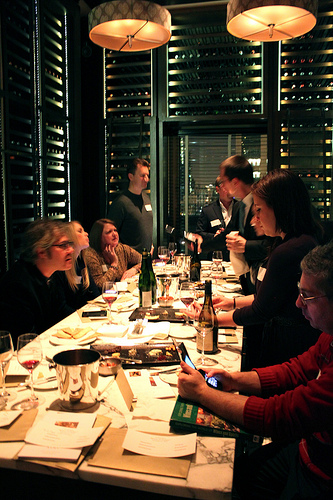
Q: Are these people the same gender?
A: No, they are both male and female.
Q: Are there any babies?
A: No, there are no babies.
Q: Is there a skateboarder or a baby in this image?
A: No, there are no babies or skateboarders.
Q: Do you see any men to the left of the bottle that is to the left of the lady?
A: Yes, there is a man to the left of the bottle.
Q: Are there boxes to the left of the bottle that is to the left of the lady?
A: No, there is a man to the left of the bottle.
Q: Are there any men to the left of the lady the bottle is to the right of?
A: Yes, there is a man to the left of the lady.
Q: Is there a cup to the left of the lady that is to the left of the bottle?
A: No, there is a man to the left of the lady.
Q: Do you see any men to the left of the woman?
A: Yes, there is a man to the left of the woman.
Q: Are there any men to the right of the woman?
A: No, the man is to the left of the woman.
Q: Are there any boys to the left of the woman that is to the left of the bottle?
A: No, there is a man to the left of the woman.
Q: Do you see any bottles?
A: Yes, there is a bottle.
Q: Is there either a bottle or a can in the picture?
A: Yes, there is a bottle.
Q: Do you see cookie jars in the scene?
A: No, there are no cookie jars.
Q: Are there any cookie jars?
A: No, there are no cookie jars.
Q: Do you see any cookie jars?
A: No, there are no cookie jars.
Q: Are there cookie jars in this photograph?
A: No, there are no cookie jars.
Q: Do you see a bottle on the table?
A: Yes, there is a bottle on the table.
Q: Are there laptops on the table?
A: No, there is a bottle on the table.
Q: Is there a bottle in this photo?
A: Yes, there is a bottle.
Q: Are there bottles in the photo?
A: Yes, there is a bottle.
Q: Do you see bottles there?
A: Yes, there is a bottle.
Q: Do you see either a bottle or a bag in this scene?
A: Yes, there is a bottle.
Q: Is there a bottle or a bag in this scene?
A: Yes, there is a bottle.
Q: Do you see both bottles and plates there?
A: Yes, there are both a bottle and a plate.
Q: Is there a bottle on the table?
A: Yes, there is a bottle on the table.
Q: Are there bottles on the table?
A: Yes, there is a bottle on the table.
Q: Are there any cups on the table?
A: No, there is a bottle on the table.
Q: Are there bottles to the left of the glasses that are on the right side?
A: Yes, there is a bottle to the left of the glasses.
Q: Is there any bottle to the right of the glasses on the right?
A: No, the bottle is to the left of the glasses.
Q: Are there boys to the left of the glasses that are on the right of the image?
A: No, there is a bottle to the left of the glasses.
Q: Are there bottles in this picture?
A: Yes, there is a bottle.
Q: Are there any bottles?
A: Yes, there is a bottle.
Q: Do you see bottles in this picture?
A: Yes, there is a bottle.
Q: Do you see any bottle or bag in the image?
A: Yes, there is a bottle.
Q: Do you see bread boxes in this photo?
A: No, there are no bread boxes.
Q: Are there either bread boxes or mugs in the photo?
A: No, there are no bread boxes or mugs.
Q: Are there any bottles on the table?
A: Yes, there is a bottle on the table.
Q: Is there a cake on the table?
A: No, there is a bottle on the table.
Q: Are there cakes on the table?
A: No, there is a bottle on the table.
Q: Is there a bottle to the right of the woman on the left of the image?
A: Yes, there is a bottle to the right of the woman.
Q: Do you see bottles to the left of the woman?
A: No, the bottle is to the right of the woman.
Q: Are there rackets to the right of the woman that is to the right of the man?
A: No, there is a bottle to the right of the woman.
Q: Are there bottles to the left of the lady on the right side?
A: Yes, there is a bottle to the left of the lady.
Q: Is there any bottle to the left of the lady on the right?
A: Yes, there is a bottle to the left of the lady.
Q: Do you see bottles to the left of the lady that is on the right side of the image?
A: Yes, there is a bottle to the left of the lady.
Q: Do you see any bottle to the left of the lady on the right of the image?
A: Yes, there is a bottle to the left of the lady.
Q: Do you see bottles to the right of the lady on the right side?
A: No, the bottle is to the left of the lady.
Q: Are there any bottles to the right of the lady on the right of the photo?
A: No, the bottle is to the left of the lady.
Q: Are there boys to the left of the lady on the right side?
A: No, there is a bottle to the left of the lady.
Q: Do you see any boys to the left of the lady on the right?
A: No, there is a bottle to the left of the lady.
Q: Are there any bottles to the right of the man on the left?
A: Yes, there is a bottle to the right of the man.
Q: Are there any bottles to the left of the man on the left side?
A: No, the bottle is to the right of the man.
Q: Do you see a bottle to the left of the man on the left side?
A: No, the bottle is to the right of the man.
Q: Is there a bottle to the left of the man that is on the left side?
A: No, the bottle is to the right of the man.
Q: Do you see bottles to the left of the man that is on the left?
A: No, the bottle is to the right of the man.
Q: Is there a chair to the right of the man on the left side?
A: No, there is a bottle to the right of the man.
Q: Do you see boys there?
A: No, there are no boys.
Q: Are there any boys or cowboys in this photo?
A: No, there are no boys or cowboys.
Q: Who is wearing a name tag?
A: The man is wearing a name tag.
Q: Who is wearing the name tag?
A: The man is wearing a name tag.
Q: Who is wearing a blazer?
A: The man is wearing a blazer.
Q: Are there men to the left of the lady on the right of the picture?
A: Yes, there is a man to the left of the lady.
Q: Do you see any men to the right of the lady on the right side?
A: No, the man is to the left of the lady.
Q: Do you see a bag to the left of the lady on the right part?
A: No, there is a man to the left of the lady.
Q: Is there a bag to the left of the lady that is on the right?
A: No, there is a man to the left of the lady.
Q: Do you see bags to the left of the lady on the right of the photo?
A: No, there is a man to the left of the lady.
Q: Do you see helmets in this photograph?
A: No, there are no helmets.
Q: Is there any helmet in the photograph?
A: No, there are no helmets.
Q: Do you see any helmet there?
A: No, there are no helmets.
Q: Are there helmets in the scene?
A: No, there are no helmets.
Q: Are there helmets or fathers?
A: No, there are no helmets or fathers.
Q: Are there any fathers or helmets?
A: No, there are no helmets or fathers.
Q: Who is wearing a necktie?
A: The man is wearing a necktie.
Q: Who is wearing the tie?
A: The man is wearing a necktie.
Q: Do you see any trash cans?
A: No, there are no trash cans.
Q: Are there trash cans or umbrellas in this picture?
A: No, there are no trash cans or umbrellas.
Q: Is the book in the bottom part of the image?
A: Yes, the book is in the bottom of the image.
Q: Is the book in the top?
A: No, the book is in the bottom of the image.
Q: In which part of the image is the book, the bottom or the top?
A: The book is in the bottom of the image.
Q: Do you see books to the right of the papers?
A: Yes, there is a book to the right of the papers.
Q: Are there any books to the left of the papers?
A: No, the book is to the right of the papers.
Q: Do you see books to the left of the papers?
A: No, the book is to the right of the papers.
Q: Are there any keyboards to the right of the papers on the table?
A: No, there is a book to the right of the papers.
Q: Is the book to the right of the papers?
A: Yes, the book is to the right of the papers.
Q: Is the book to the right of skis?
A: No, the book is to the right of the papers.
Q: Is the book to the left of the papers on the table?
A: No, the book is to the right of the papers.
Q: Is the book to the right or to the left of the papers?
A: The book is to the right of the papers.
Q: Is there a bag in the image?
A: No, there are no bags.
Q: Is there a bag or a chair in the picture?
A: No, there are no bags or chairs.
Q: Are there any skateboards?
A: No, there are no skateboards.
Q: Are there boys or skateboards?
A: No, there are no skateboards or boys.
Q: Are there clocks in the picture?
A: No, there are no clocks.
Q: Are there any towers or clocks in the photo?
A: No, there are no clocks or towers.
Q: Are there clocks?
A: No, there are no clocks.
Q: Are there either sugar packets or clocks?
A: No, there are no clocks or sugar packets.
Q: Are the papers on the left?
A: Yes, the papers are on the left of the image.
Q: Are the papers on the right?
A: No, the papers are on the left of the image.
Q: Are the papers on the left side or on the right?
A: The papers are on the left of the image.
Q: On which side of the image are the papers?
A: The papers are on the left of the image.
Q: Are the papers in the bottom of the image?
A: Yes, the papers are in the bottom of the image.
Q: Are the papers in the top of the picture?
A: No, the papers are in the bottom of the image.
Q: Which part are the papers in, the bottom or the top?
A: The papers are in the bottom of the image.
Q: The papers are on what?
A: The papers are on the table.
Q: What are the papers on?
A: The papers are on the table.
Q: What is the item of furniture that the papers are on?
A: The piece of furniture is a table.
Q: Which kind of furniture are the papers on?
A: The papers are on the table.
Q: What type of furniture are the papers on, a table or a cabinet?
A: The papers are on a table.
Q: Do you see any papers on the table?
A: Yes, there are papers on the table.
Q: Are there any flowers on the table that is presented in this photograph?
A: No, there are papers on the table.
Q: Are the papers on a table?
A: Yes, the papers are on a table.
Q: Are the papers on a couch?
A: No, the papers are on a table.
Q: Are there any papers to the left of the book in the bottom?
A: Yes, there are papers to the left of the book.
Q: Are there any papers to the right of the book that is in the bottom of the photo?
A: No, the papers are to the left of the book.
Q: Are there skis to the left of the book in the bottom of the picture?
A: No, there are papers to the left of the book.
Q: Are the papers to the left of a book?
A: Yes, the papers are to the left of a book.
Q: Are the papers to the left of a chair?
A: No, the papers are to the left of a book.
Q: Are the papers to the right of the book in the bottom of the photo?
A: No, the papers are to the left of the book.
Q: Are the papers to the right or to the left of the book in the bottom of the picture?
A: The papers are to the left of the book.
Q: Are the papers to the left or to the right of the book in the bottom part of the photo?
A: The papers are to the left of the book.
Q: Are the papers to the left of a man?
A: Yes, the papers are to the left of a man.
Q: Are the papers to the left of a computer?
A: No, the papers are to the left of a man.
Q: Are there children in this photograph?
A: No, there are no children.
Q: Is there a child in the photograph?
A: No, there are no children.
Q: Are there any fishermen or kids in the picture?
A: No, there are no kids or fishermen.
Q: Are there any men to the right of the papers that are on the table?
A: Yes, there is a man to the right of the papers.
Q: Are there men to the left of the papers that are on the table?
A: No, the man is to the right of the papers.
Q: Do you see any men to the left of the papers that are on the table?
A: No, the man is to the right of the papers.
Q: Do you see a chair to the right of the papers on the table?
A: No, there is a man to the right of the papers.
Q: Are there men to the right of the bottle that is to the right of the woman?
A: Yes, there is a man to the right of the bottle.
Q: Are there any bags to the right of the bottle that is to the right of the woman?
A: No, there is a man to the right of the bottle.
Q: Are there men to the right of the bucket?
A: Yes, there is a man to the right of the bucket.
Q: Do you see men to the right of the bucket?
A: Yes, there is a man to the right of the bucket.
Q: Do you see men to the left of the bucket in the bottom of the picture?
A: No, the man is to the right of the bucket.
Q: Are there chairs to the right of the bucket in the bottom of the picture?
A: No, there is a man to the right of the bucket.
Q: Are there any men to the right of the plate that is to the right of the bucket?
A: Yes, there is a man to the right of the plate.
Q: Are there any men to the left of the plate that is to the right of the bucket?
A: No, the man is to the right of the plate.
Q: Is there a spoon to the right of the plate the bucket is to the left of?
A: No, there is a man to the right of the plate.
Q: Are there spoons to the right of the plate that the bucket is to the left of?
A: No, there is a man to the right of the plate.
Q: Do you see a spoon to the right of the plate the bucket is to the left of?
A: No, there is a man to the right of the plate.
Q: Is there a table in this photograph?
A: Yes, there is a table.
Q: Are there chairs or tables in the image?
A: Yes, there is a table.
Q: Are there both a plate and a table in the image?
A: Yes, there are both a table and a plate.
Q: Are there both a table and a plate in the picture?
A: Yes, there are both a table and a plate.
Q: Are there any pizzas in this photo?
A: No, there are no pizzas.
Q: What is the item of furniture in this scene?
A: The piece of furniture is a table.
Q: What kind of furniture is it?
A: The piece of furniture is a table.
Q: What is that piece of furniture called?
A: This is a table.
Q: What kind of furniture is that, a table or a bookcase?
A: This is a table.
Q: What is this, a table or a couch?
A: This is a table.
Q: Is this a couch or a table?
A: This is a table.